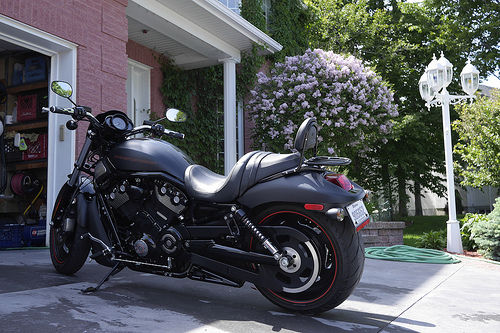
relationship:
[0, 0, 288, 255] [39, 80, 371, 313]
house behind motorcycle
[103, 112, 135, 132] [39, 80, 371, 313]
gauges on motorcycle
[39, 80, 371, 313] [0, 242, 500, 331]
motorcycle in driveway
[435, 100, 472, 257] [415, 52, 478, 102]
lamp post for lamps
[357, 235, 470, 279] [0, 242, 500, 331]
hose on driveway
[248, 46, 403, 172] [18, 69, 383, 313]
lilac bush behind motorcycle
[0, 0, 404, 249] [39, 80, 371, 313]
house with motorcycle